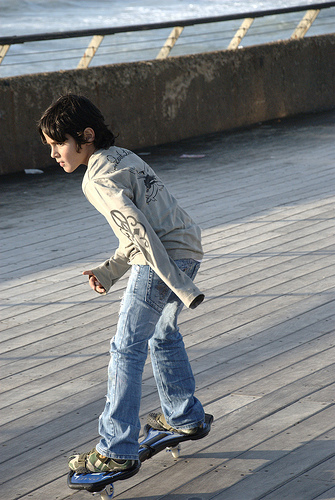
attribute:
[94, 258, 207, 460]
jeans — blue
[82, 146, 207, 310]
sweater — grey, gray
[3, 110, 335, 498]
floor — wood, grey, wooden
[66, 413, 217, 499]
skateboard — blue, black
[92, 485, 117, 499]
wheels — white, black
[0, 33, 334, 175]
wall — brown, concrete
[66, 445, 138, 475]
shoes — brown, green, gray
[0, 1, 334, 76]
railing — black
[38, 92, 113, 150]
hair — brown, black